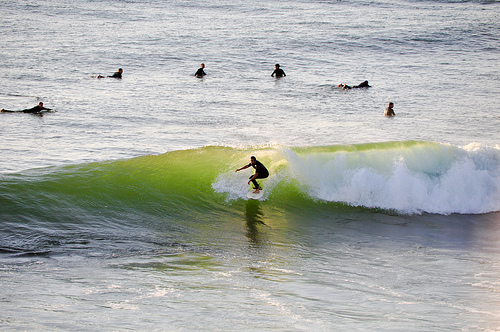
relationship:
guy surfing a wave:
[235, 156, 270, 194] [7, 137, 496, 234]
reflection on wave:
[151, 147, 308, 204] [111, 142, 498, 219]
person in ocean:
[0, 102, 57, 117] [13, 8, 495, 316]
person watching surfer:
[0, 102, 57, 117] [225, 152, 286, 208]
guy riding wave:
[235, 156, 270, 194] [2, 131, 499, 226]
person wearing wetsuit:
[336, 79, 370, 88] [348, 82, 370, 89]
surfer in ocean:
[91, 67, 124, 81] [13, 8, 495, 316]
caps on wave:
[283, 141, 499, 219] [2, 140, 498, 216]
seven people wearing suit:
[30, 54, 430, 199] [255, 160, 267, 189]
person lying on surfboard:
[14, 103, 46, 113] [247, 183, 269, 200]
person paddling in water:
[338, 80, 372, 90] [418, 22, 495, 151]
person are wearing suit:
[0, 102, 57, 117] [247, 160, 269, 189]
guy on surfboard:
[232, 155, 270, 194] [241, 180, 268, 205]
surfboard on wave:
[241, 180, 268, 205] [2, 140, 498, 216]